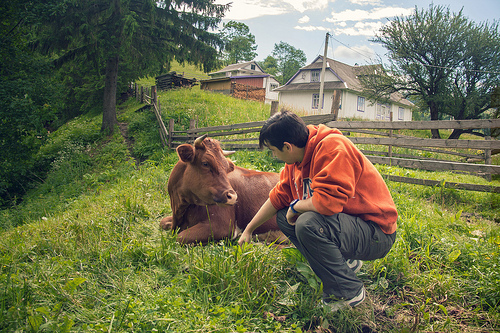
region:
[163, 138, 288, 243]
a brown cow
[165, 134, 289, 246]
cow resting on ground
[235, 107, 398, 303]
a man kneeling down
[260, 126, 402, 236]
an orange sweatshirt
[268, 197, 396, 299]
grey pair of men's pants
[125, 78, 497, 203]
long wooden slat fence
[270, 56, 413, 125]
white house in distance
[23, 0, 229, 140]
large tree in distance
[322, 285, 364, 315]
a white men's shoe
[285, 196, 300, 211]
a black watch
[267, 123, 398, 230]
an orange hooded sweatshirt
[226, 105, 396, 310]
man crouching next to cow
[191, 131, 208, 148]
pointy horns on cow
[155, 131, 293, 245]
brown cow sitting next to man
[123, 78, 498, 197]
wooden fence behind man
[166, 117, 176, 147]
weathered wooden fence post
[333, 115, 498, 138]
long wooden fence railing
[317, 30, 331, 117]
tall utility pole in front of house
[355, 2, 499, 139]
tree to the right of house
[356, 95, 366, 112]
window on house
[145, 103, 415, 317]
a guy and a cow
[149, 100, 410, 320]
a guy squatting looking at the cow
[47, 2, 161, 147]
a tree in a hill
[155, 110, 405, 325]
a cow looking at the person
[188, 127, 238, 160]
horns of the cow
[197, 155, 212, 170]
an eye of the cow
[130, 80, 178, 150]
fence in the background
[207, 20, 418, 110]
houses in the background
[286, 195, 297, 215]
a watch the guy is using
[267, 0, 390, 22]
clouds in the background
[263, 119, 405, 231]
an orange seatshirt on a man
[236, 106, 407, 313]
a man bending down next to a cow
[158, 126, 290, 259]
a brown cow laying in the grass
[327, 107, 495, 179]
a wooden fence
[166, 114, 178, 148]
a wooden fence post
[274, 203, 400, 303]
gray pants on a man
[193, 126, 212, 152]
a horn on a cow's head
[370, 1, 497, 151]
a tree in a yard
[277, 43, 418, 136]
a white house in a yard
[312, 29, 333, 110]
a utility pole next to a house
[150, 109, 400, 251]
Man and animal staring at each other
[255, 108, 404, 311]
Man stooping in grass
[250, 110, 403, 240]
Man wearing orange hoodie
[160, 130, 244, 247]
Brown cow with small horns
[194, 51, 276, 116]
Small house on a hill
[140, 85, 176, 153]
Wooden rail fence slanted on hill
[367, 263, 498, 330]
Green and brown grassy field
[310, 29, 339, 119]
Electrical pole behind house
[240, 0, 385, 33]
Sunlight filtering through wispy clouds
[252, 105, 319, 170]
Male with brown hair